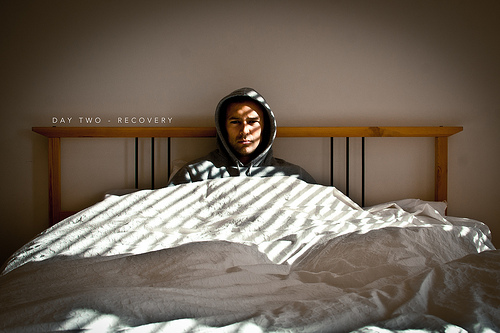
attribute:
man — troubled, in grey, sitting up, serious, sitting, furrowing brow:
[164, 85, 319, 197]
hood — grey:
[210, 86, 280, 163]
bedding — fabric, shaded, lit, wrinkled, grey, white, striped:
[2, 168, 499, 332]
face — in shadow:
[223, 100, 265, 156]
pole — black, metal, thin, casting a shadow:
[132, 136, 144, 190]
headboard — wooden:
[29, 119, 466, 228]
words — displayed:
[49, 114, 177, 127]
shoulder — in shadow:
[163, 149, 227, 189]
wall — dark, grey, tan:
[0, 1, 499, 251]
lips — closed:
[233, 138, 255, 146]